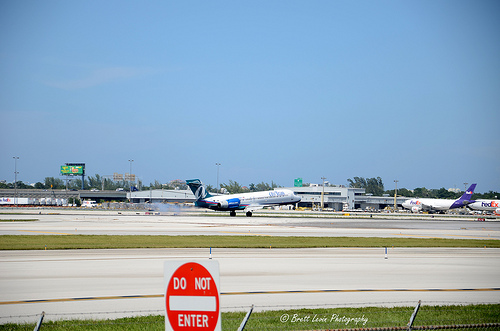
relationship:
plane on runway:
[185, 178, 302, 218] [2, 203, 498, 241]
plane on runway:
[185, 178, 302, 218] [2, 199, 498, 236]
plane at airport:
[185, 178, 302, 218] [12, 175, 135, 215]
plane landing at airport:
[182, 177, 302, 217] [2, 177, 494, 299]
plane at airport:
[401, 183, 478, 215] [10, 181, 493, 324]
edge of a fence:
[320, 239, 353, 258] [2, 296, 499, 329]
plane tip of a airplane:
[288, 185, 303, 202] [174, 169, 308, 215]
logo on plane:
[476, 196, 497, 213] [395, 179, 477, 218]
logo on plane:
[476, 196, 497, 213] [184, 173, 301, 218]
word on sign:
[170, 270, 187, 295] [164, 260, 222, 325]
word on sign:
[172, 276, 187, 290] [160, 257, 222, 328]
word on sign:
[191, 273, 212, 293] [158, 257, 240, 324]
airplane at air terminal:
[185, 178, 301, 218] [3, 0, 499, 325]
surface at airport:
[208, 236, 429, 304] [10, 181, 493, 324]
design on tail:
[184, 178, 209, 201] [188, 177, 212, 200]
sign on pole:
[59, 161, 84, 177] [72, 175, 84, 185]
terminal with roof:
[279, 184, 366, 209] [276, 180, 367, 192]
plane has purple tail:
[396, 187, 489, 221] [451, 182, 480, 209]